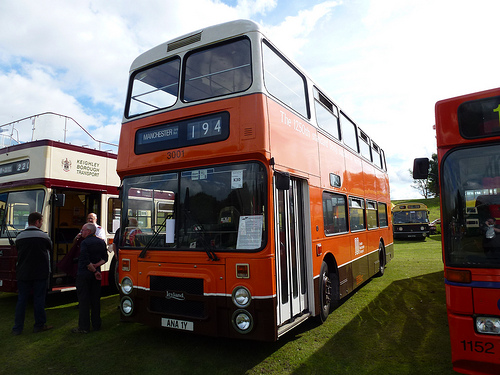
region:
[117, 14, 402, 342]
orange and white double decker bus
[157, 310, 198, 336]
black letters on white background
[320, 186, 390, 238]
lower windows on side of bus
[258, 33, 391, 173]
upper side windows of a bus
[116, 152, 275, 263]
windshield on an orange and white bus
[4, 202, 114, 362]
people standing next to the bus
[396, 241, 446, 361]
green grass between buses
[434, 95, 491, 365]
portion of an orange bus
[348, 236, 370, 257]
white lettering on an orange side of a bus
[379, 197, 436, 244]
yellow and black bus in the background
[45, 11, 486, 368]
A bus in a big city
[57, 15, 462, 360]
The bus is carrying passengers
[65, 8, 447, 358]
A double decker bus is parked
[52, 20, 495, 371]
A bus is parked on the grass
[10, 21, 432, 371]
People are standing next to a bus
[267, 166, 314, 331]
The bus has a door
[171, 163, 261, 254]
The windshield of a bus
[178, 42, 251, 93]
The window of a bus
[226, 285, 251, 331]
The headlights of a bus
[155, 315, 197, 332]
The license plate of a bus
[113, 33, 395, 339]
an orange white and black bus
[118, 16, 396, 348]
a double decker bus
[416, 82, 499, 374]
a parked red bus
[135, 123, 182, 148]
a bus destination sign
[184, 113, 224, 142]
a bus number sign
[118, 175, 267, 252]
a bus front windshield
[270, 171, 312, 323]
a bus entry exit doors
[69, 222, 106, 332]
man standing in grass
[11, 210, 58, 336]
man standing in grass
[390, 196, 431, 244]
a yellow bus in distance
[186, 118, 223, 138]
the number 194 in white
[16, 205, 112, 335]
a group of people talking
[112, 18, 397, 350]
an orange double decker bus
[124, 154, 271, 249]
a bus windshield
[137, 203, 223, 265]
a pair of windshield wipers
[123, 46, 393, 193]
the top part of an orange bus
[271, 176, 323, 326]
a white bus door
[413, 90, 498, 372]
part of a red bus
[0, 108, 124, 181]
an observation roof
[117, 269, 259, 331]
the grill of a bus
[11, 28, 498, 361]
Buses parked next to each other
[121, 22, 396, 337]
The bus is double decker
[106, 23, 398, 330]
The bus is white, orange and black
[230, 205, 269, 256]
White paper on the wind shield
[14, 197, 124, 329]
People standing by the buses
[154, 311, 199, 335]
White and black license plate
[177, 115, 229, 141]
Number 194 on front of bus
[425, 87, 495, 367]
The bus is red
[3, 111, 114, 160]
Railing on top of the bus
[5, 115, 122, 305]
The bus is white and red